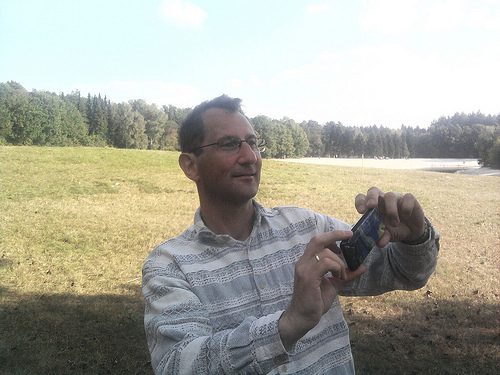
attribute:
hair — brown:
[176, 92, 239, 157]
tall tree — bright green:
[139, 101, 171, 156]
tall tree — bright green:
[124, 105, 159, 151]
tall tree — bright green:
[97, 99, 131, 152]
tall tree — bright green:
[76, 93, 104, 148]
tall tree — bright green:
[50, 84, 92, 148]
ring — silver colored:
[315, 252, 324, 263]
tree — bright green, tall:
[1, 84, 53, 148]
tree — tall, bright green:
[47, 97, 87, 139]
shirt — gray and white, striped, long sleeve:
[137, 201, 441, 373]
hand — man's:
[286, 228, 366, 333]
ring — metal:
[309, 250, 329, 268]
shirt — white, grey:
[168, 223, 289, 305]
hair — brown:
[180, 93, 245, 155]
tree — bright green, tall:
[266, 118, 298, 158]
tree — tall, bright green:
[300, 122, 321, 155]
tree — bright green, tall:
[430, 120, 459, 151]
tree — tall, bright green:
[368, 126, 388, 156]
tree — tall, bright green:
[80, 92, 113, 148]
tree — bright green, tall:
[111, 104, 143, 150]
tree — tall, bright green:
[50, 95, 87, 147]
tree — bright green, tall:
[365, 127, 386, 157]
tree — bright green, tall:
[80, 95, 108, 147]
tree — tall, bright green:
[322, 115, 351, 155]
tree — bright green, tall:
[140, 105, 170, 150]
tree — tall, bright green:
[1, 79, 43, 145]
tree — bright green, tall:
[33, 85, 63, 145]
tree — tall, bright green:
[85, 95, 111, 146]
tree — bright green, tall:
[289, 122, 315, 158]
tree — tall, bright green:
[108, 100, 134, 149]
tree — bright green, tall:
[0, 87, 39, 145]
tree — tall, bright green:
[138, 99, 167, 149]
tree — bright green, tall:
[302, 119, 326, 156]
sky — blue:
[1, 1, 163, 73]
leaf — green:
[301, 135, 306, 137]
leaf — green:
[146, 115, 154, 125]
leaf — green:
[91, 105, 100, 115]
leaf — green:
[118, 108, 137, 114]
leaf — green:
[16, 96, 22, 108]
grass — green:
[15, 314, 113, 360]